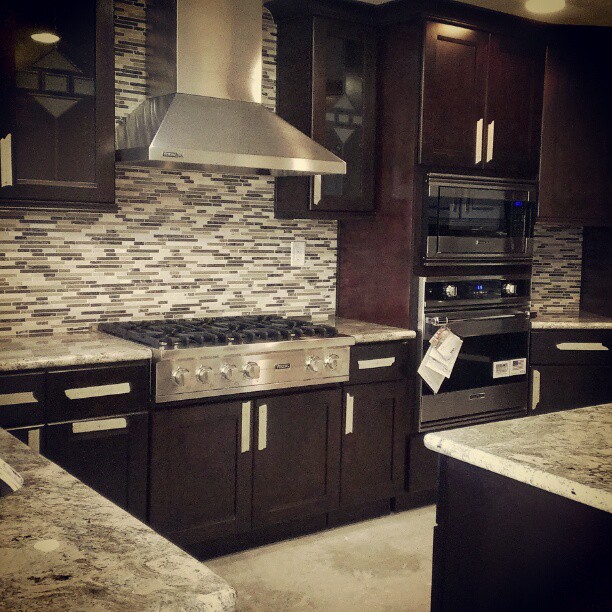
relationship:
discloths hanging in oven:
[407, 321, 462, 398] [419, 326, 535, 430]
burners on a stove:
[102, 284, 349, 342] [176, 333, 279, 424]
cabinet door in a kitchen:
[213, 386, 290, 493] [133, 288, 366, 545]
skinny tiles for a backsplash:
[128, 253, 225, 308] [88, 209, 260, 351]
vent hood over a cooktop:
[134, 62, 278, 132] [141, 302, 335, 353]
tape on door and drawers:
[8, 371, 133, 452] [30, 375, 149, 499]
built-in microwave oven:
[415, 181, 528, 245] [507, 188, 554, 226]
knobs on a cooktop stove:
[151, 345, 280, 408] [168, 286, 361, 511]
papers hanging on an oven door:
[407, 316, 470, 387] [429, 306, 496, 350]